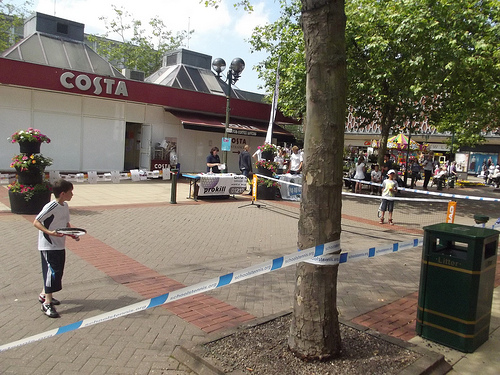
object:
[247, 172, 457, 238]
net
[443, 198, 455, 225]
support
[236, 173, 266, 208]
support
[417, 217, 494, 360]
can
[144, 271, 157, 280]
brick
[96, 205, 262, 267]
ground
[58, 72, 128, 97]
sign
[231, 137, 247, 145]
sign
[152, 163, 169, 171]
sign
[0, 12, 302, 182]
building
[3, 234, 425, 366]
tape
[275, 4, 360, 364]
tree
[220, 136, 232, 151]
sign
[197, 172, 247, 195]
sign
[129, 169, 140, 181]
sign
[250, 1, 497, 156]
leaves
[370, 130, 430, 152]
umbrella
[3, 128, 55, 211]
tiered plant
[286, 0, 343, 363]
trunk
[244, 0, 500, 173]
tree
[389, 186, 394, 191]
tennis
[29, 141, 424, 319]
court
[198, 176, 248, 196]
banner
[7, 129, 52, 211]
planter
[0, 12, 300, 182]
restaurant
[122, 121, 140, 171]
entry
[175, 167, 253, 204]
table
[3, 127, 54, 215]
flower pot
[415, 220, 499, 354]
trash can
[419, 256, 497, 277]
stripes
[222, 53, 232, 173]
pole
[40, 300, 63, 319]
shoes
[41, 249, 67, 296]
black shorts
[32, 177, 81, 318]
boy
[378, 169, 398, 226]
boy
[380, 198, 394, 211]
black shorts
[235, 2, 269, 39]
clouds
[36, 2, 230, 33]
clouds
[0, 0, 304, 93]
sky